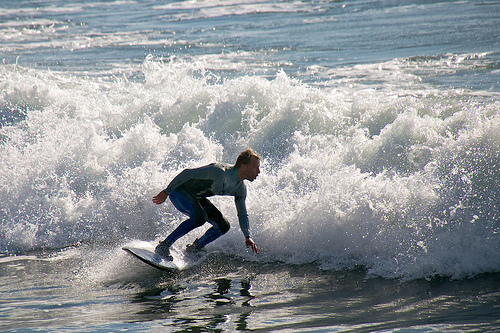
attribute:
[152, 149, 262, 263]
man — blonde, surfing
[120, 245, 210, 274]
board — white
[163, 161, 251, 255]
suit — blue, green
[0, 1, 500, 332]
water — splashing, vigorous, turbulent, tumultuous, lively, spirited, zealous, breaking, blue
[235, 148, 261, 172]
hair — blonde, short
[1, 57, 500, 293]
wave — huge, splashing